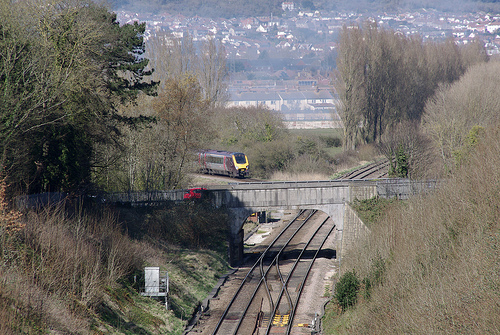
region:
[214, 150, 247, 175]
this is a train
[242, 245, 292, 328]
this is a railway line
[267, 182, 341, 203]
this is a bridg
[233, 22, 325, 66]
these are the buildings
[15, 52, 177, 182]
these are the trees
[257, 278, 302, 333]
the railway line are metallic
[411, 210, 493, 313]
the trees are grey in colour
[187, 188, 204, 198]
the train is red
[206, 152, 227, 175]
the train is grey in color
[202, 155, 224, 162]
these are the windows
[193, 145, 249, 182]
a train is on the tracks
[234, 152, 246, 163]
window on the front of a train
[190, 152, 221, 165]
windows on the side of a train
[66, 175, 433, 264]
a small concrete bridge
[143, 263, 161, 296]
a silver metal box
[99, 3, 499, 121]
a hillside of buildings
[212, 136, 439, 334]
train tracks going around a bend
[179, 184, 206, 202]
red paint on concrete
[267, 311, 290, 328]
yellow tool on a track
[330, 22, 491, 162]
trees that are dead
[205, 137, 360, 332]
trains are at a crossway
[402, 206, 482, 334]
the plants are beside the road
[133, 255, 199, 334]
the tank is white in color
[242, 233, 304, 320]
the railways are crosing each other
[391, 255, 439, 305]
the plants are dried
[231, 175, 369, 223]
the road is above the ailway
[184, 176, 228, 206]
a car is passing on the road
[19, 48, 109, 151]
trees are green in color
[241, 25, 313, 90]
buildings are seen at the background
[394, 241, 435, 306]
part of a grass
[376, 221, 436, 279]
part of a grass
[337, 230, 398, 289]
part of a grass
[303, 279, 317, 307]
edge of a rail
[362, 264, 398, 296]
part of a grass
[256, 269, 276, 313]
edge of a rail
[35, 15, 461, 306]
this is a rural area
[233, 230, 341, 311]
these are train tracks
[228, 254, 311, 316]
there are two sets of tracks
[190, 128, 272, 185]
this is a train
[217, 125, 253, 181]
the train front is yellow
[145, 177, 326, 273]
this is a train bridge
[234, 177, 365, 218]
the bridge is gray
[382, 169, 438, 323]
this is tall grass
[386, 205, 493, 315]
the tall grass is brown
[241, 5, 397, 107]
this is an urban area